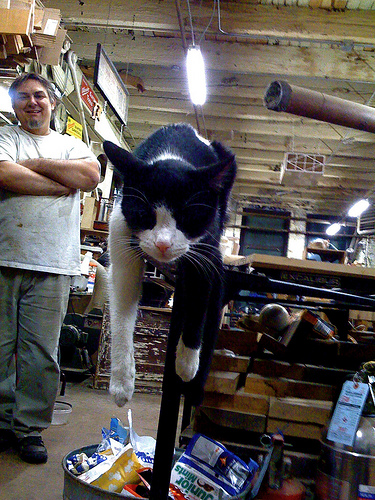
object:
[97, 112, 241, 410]
cat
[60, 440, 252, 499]
box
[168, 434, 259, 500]
junior mints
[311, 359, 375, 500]
fire extinguisher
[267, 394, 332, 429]
lumber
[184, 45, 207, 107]
light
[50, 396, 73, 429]
bowl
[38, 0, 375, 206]
ceiling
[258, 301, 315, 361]
ball and hitch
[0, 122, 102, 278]
shirt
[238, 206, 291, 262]
window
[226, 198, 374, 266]
back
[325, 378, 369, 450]
tag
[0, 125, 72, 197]
arms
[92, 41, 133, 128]
sign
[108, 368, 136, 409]
foot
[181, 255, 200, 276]
whiskers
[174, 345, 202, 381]
foot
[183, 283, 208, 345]
black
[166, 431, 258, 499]
packet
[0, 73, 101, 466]
man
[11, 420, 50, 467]
black shoe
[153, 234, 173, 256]
nose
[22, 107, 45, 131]
moustache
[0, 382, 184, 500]
floor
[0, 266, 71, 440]
blue jeans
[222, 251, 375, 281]
edge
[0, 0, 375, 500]
store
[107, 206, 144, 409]
leg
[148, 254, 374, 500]
furniture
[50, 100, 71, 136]
clocks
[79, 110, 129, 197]
wall